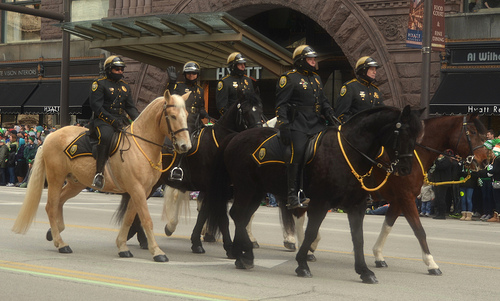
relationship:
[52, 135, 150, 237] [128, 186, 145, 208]
horse has leg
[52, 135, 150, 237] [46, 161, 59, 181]
horse has leg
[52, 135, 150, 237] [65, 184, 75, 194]
horse has leg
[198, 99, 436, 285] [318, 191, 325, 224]
horse has leg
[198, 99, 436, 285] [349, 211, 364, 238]
horse has leg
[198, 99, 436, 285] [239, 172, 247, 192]
horse has leg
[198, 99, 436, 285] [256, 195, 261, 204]
horse has leg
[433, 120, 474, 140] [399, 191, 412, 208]
horse has leg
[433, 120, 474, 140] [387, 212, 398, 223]
horse has leg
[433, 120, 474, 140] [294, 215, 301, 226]
horse has leg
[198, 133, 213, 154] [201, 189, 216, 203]
horse has leg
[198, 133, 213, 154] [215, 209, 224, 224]
horse has leg